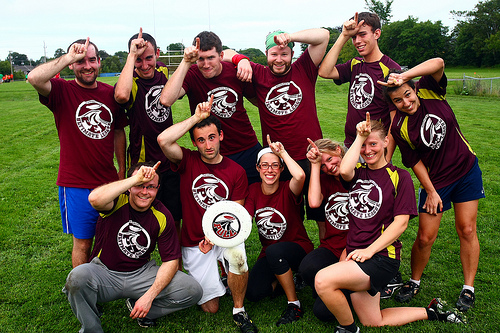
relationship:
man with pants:
[65, 161, 203, 333] [64, 254, 196, 328]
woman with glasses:
[249, 147, 296, 286] [253, 161, 290, 168]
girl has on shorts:
[342, 115, 414, 331] [371, 246, 397, 286]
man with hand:
[126, 38, 166, 148] [131, 37, 143, 56]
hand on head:
[131, 37, 143, 56] [122, 30, 159, 78]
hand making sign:
[131, 37, 143, 56] [313, 152, 391, 220]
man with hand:
[253, 21, 320, 134] [271, 27, 291, 52]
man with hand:
[320, 12, 402, 152] [338, 15, 360, 38]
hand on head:
[338, 15, 360, 38] [362, 17, 379, 52]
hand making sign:
[338, 15, 360, 38] [351, 12, 362, 32]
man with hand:
[95, 165, 160, 290] [132, 157, 163, 186]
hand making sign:
[132, 157, 163, 186] [150, 158, 161, 174]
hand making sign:
[266, 137, 288, 165] [261, 127, 272, 146]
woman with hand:
[249, 147, 296, 286] [266, 137, 288, 165]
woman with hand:
[366, 90, 493, 287] [375, 74, 405, 89]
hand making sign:
[375, 74, 405, 89] [424, 101, 453, 167]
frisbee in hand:
[204, 191, 254, 252] [197, 241, 212, 255]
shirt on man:
[37, 73, 132, 187] [24, 31, 131, 275]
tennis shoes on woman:
[392, 264, 485, 316] [366, 90, 493, 287]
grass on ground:
[1, 69, 497, 332] [2, 68, 494, 332]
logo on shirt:
[75, 100, 113, 140] [52, 82, 124, 184]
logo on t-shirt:
[120, 223, 146, 257] [105, 204, 161, 279]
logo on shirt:
[75, 99, 112, 137] [39, 77, 120, 185]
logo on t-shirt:
[205, 86, 240, 121] [185, 64, 260, 151]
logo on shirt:
[421, 114, 446, 149] [390, 71, 475, 188]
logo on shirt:
[265, 77, 305, 117] [244, 60, 318, 143]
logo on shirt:
[173, 154, 237, 218] [170, 146, 250, 247]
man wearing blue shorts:
[33, 36, 130, 241] [58, 186, 99, 240]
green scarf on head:
[255, 34, 287, 51] [266, 31, 295, 76]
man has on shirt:
[65, 161, 203, 333] [168, 139, 283, 240]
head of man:
[156, 91, 266, 326] [177, 118, 226, 160]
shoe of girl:
[424, 297, 472, 325] [314, 111, 467, 332]